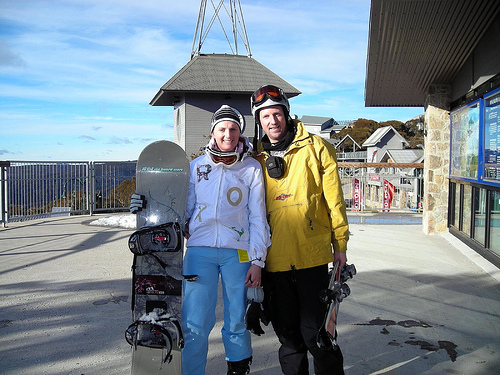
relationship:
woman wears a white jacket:
[187, 105, 273, 374] [187, 152, 272, 264]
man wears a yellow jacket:
[246, 84, 347, 375] [252, 120, 352, 271]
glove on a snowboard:
[126, 190, 146, 214] [124, 144, 194, 375]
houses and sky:
[299, 113, 422, 211] [1, 0, 426, 159]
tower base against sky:
[192, 0, 256, 59] [1, 0, 426, 159]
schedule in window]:
[482, 86, 498, 182] [450, 81, 500, 272]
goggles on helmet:
[252, 85, 282, 103] [253, 88, 293, 121]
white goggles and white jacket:
[208, 148, 241, 166] [187, 152, 272, 264]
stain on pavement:
[354, 317, 477, 366] [1, 214, 500, 374]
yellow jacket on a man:
[252, 120, 352, 271] [246, 84, 347, 375]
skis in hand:
[315, 257, 359, 349] [331, 241, 349, 277]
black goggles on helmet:
[252, 85, 282, 103] [253, 88, 293, 121]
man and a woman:
[246, 84, 347, 375] [187, 105, 273, 374]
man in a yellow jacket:
[246, 84, 347, 375] [252, 120, 352, 271]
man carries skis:
[246, 84, 347, 375] [315, 257, 359, 349]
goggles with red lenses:
[252, 85, 282, 103] [257, 90, 279, 99]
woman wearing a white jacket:
[187, 105, 273, 374] [187, 152, 272, 264]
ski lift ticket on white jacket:
[237, 248, 253, 262] [187, 152, 272, 264]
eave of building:
[363, 2, 500, 106] [425, 16, 500, 290]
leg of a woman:
[182, 243, 217, 375] [187, 105, 273, 374]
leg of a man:
[262, 271, 307, 374] [246, 84, 347, 375]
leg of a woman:
[223, 250, 256, 373] [187, 105, 273, 374]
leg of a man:
[300, 272, 347, 372] [246, 84, 347, 375]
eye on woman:
[218, 126, 225, 135] [187, 105, 273, 374]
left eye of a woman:
[230, 125, 240, 137] [187, 105, 273, 374]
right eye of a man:
[265, 112, 270, 121] [246, 84, 347, 375]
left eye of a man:
[275, 112, 285, 120] [246, 84, 347, 375]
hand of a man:
[331, 241, 349, 277] [246, 84, 347, 375]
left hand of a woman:
[246, 264, 265, 289] [187, 105, 273, 374]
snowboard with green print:
[124, 144, 194, 375] [142, 164, 185, 176]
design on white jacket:
[195, 160, 214, 185] [187, 152, 272, 264]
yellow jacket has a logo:
[252, 120, 352, 271] [273, 191, 292, 205]